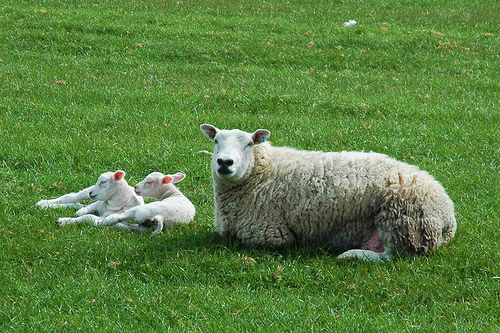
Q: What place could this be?
A: It is a field.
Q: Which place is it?
A: It is a field.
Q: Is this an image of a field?
A: Yes, it is showing a field.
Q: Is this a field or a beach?
A: It is a field.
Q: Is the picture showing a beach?
A: No, the picture is showing a field.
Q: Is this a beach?
A: No, it is a field.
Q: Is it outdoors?
A: Yes, it is outdoors.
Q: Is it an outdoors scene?
A: Yes, it is outdoors.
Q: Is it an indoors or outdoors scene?
A: It is outdoors.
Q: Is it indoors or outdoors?
A: It is outdoors.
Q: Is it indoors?
A: No, it is outdoors.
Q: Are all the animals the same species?
A: Yes, all the animals are sheep.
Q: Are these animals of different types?
A: No, all the animals are sheep.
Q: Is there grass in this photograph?
A: Yes, there is grass.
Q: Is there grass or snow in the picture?
A: Yes, there is grass.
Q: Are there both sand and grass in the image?
A: No, there is grass but no sand.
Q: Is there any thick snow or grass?
A: Yes, there is thick grass.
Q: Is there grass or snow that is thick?
A: Yes, the grass is thick.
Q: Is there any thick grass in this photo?
A: Yes, there is thick grass.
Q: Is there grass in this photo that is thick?
A: Yes, there is grass that is thick.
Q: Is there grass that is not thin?
A: Yes, there is thick grass.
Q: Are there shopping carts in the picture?
A: No, there are no shopping carts.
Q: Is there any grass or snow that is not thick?
A: No, there is grass but it is thick.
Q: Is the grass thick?
A: Yes, the grass is thick.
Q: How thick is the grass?
A: The grass is thick.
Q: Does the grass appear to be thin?
A: No, the grass is thick.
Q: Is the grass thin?
A: No, the grass is thick.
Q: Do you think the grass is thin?
A: No, the grass is thick.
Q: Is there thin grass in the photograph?
A: No, there is grass but it is thick.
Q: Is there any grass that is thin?
A: No, there is grass but it is thick.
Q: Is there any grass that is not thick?
A: No, there is grass but it is thick.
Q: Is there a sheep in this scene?
A: Yes, there is a sheep.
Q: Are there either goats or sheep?
A: Yes, there is a sheep.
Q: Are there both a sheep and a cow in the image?
A: No, there is a sheep but no cows.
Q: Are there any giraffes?
A: No, there are no giraffes.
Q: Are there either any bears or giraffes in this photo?
A: No, there are no giraffes or bears.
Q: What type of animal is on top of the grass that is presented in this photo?
A: The animal is a sheep.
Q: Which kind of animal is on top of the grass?
A: The animal is a sheep.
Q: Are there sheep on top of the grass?
A: Yes, there is a sheep on top of the grass.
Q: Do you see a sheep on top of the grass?
A: Yes, there is a sheep on top of the grass.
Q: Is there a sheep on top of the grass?
A: Yes, there is a sheep on top of the grass.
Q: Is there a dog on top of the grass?
A: No, there is a sheep on top of the grass.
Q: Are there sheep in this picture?
A: Yes, there is a sheep.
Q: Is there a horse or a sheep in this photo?
A: Yes, there is a sheep.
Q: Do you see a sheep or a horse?
A: Yes, there is a sheep.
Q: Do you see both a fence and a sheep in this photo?
A: No, there is a sheep but no fences.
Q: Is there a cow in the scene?
A: No, there are no cows.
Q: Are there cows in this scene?
A: No, there are no cows.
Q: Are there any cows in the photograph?
A: No, there are no cows.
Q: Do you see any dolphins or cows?
A: No, there are no cows or dolphins.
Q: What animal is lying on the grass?
A: The sheep is lying on the grass.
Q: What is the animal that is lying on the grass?
A: The animal is a sheep.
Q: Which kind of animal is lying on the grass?
A: The animal is a sheep.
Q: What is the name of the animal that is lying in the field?
A: The animal is a sheep.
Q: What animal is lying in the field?
A: The animal is a sheep.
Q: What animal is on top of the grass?
A: The animal is a sheep.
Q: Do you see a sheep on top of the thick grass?
A: Yes, there is a sheep on top of the grass.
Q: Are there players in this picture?
A: No, there are no players.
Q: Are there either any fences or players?
A: No, there are no players or fences.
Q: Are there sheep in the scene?
A: Yes, there is a sheep.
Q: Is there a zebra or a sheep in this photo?
A: Yes, there is a sheep.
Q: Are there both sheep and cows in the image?
A: No, there is a sheep but no cows.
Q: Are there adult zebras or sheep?
A: Yes, there is an adult sheep.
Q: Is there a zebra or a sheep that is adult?
A: Yes, the sheep is adult.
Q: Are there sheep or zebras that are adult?
A: Yes, the sheep is adult.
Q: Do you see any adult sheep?
A: Yes, there is an adult sheep.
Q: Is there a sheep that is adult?
A: Yes, there is a sheep that is adult.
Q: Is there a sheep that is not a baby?
A: Yes, there is a adult sheep.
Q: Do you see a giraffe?
A: No, there are no giraffes.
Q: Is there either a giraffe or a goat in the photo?
A: No, there are no giraffes or goats.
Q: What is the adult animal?
A: The animal is a sheep.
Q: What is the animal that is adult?
A: The animal is a sheep.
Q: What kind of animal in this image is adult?
A: The animal is a sheep.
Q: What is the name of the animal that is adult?
A: The animal is a sheep.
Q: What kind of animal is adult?
A: The animal is a sheep.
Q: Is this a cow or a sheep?
A: This is a sheep.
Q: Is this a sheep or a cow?
A: This is a sheep.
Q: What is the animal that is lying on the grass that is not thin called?
A: The animal is a sheep.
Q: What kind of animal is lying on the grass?
A: The animal is a sheep.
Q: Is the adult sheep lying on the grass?
A: Yes, the sheep is lying on the grass.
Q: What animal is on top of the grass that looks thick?
A: The sheep is on top of the grass.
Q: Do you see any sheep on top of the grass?
A: Yes, there is a sheep on top of the grass.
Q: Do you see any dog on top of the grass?
A: No, there is a sheep on top of the grass.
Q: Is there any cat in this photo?
A: No, there are no cats.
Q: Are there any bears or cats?
A: No, there are no cats or bears.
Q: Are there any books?
A: No, there are no books.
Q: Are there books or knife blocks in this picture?
A: No, there are no books or knife blocks.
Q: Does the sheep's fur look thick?
A: Yes, the fur is thick.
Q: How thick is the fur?
A: The fur is thick.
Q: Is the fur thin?
A: No, the fur is thick.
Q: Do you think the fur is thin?
A: No, the fur is thick.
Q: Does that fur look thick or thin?
A: The fur is thick.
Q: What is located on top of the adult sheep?
A: The fur is on top of the sheep.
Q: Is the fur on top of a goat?
A: No, the fur is on top of a sheep.